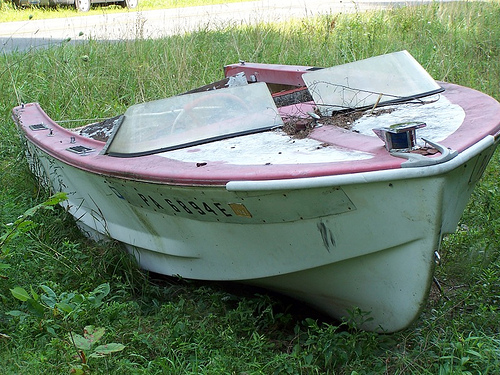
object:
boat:
[10, 50, 500, 334]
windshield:
[99, 80, 284, 158]